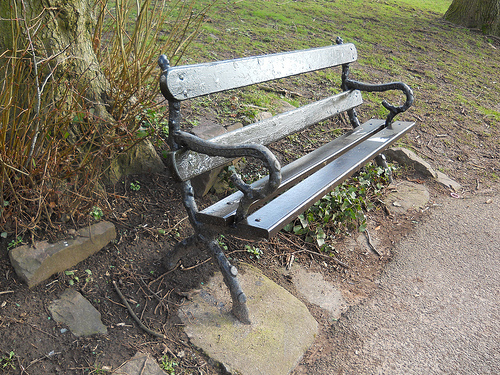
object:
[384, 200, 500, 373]
pathway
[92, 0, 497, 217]
land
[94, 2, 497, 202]
grass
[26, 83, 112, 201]
tree trunk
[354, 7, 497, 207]
grass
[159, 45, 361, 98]
top part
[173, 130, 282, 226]
arm rest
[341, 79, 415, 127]
arm rest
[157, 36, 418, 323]
bench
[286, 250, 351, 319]
rocks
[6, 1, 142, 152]
tree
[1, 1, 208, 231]
grass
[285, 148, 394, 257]
shrub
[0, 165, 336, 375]
dirt patch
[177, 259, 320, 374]
block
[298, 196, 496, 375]
cement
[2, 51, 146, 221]
trunk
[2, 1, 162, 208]
tree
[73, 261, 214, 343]
sticks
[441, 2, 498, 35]
trunk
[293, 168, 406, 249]
weeds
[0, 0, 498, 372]
ground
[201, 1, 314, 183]
grass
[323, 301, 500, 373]
pavement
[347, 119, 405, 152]
shadow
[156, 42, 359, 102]
planks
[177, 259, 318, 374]
pavers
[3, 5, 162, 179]
treetrunk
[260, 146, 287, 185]
metal end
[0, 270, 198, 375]
ground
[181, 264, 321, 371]
slabs